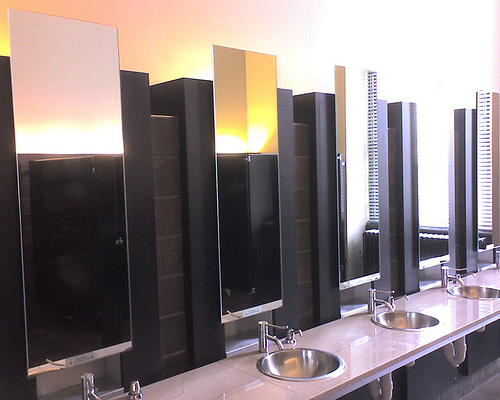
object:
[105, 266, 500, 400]
counter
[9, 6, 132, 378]
mirror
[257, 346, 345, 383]
sink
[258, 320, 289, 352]
faucet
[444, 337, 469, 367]
pipe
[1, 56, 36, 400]
wall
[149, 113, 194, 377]
wall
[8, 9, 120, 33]
top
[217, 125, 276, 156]
reflection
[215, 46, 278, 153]
effect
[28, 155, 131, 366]
door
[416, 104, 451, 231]
window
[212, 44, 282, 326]
mirror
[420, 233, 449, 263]
radiator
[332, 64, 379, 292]
mirror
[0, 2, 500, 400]
scene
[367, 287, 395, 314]
tap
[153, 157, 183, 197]
panel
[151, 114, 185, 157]
brick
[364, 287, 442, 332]
sets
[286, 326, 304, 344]
despenser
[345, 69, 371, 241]
sunlight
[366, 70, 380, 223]
blinds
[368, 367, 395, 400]
pipe